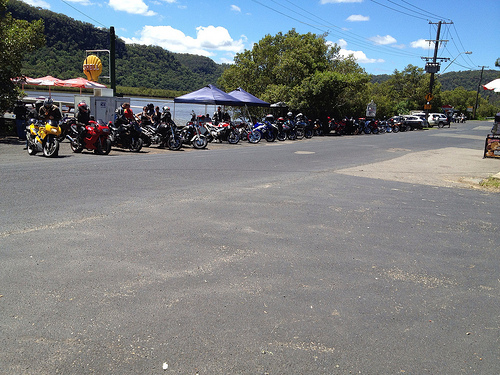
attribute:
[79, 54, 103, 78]
sign — yellow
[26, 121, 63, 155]
motorcycle — yellow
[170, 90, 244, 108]
tarp — blue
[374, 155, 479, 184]
asphalt — gray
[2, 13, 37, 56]
tree — green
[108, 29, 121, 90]
pole — wooden, large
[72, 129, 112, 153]
motorcycle — red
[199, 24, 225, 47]
cloud — white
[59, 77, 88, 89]
umbrella — orange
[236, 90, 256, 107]
tarp — purple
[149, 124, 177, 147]
motorcycle — parked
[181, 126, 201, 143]
motorcycle — parked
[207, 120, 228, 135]
motorcycle — parked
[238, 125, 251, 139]
motorcycle — parked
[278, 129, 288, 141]
motorcycle — parked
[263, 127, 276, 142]
motorcycle — parked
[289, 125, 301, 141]
motorcycle — parked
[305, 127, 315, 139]
motorcycle — parked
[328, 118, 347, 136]
motorcycle — parked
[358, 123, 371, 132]
motorcycle — parked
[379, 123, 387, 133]
motorcycle — parked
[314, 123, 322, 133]
motorcycle — parked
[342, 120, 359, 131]
motorcycle — parked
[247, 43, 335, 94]
tree — green